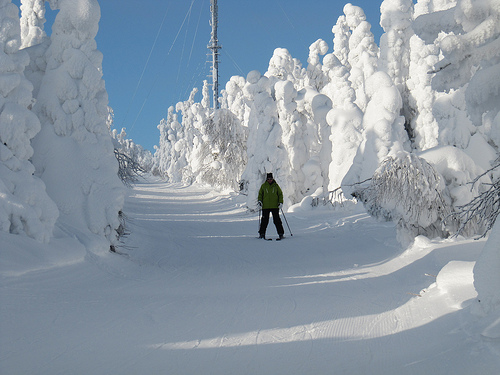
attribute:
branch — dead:
[119, 152, 148, 167]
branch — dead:
[117, 166, 123, 179]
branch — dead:
[132, 169, 147, 180]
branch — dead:
[124, 166, 134, 185]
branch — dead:
[123, 164, 148, 173]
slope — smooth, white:
[101, 180, 267, 365]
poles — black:
[252, 201, 297, 230]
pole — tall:
[209, 2, 222, 114]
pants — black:
[254, 207, 301, 244]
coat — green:
[248, 181, 289, 211]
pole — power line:
[206, 2, 223, 111]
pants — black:
[259, 207, 285, 237]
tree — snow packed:
[344, 4, 416, 200]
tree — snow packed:
[319, 13, 356, 69]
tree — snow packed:
[318, 49, 368, 201]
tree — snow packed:
[304, 30, 329, 89]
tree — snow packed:
[270, 76, 321, 206]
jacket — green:
[256, 179, 284, 212]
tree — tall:
[240, 70, 292, 205]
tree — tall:
[317, 45, 363, 202]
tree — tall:
[376, 0, 415, 110]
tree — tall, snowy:
[34, 1, 123, 244]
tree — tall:
[2, 1, 59, 237]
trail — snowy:
[3, 173, 499, 373]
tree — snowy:
[344, 73, 413, 198]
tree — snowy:
[312, 51, 378, 200]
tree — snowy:
[415, 5, 497, 236]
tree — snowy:
[260, 52, 325, 200]